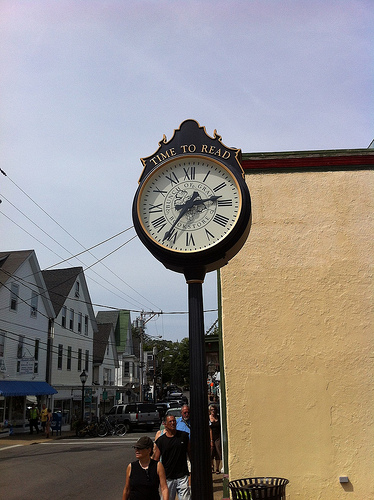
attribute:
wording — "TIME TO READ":
[144, 138, 234, 167]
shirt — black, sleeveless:
[151, 430, 188, 476]